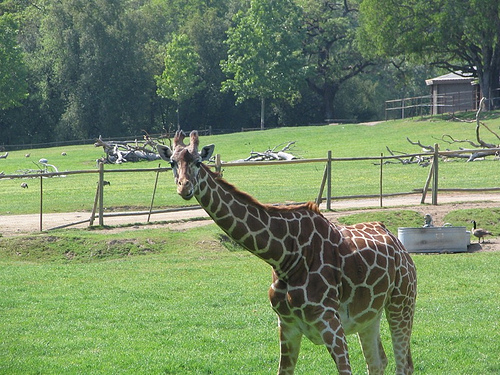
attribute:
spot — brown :
[208, 183, 261, 235]